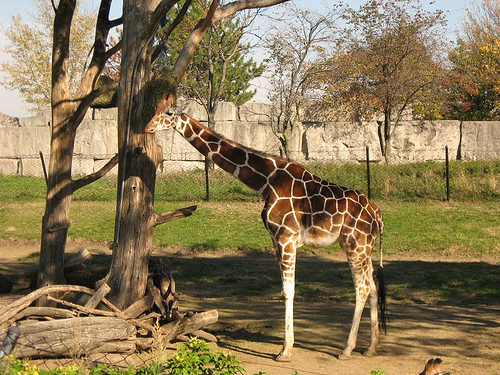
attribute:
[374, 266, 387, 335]
hairs — long, black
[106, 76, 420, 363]
giraffe — penned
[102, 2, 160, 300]
trunk — tree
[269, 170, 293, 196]
polygon — cream, brown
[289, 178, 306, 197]
polygon — cream, brown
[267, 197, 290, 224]
polygon — cream, brown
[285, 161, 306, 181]
polygon — cream, brown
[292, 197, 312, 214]
polygon — brown, cream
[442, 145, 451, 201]
post — black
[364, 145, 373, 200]
post — black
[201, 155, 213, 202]
post — black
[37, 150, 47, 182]
post — black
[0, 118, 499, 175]
wall — slabs, concrete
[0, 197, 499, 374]
enclosure — zoo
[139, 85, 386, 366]
giraffe — standing, baby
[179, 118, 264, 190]
neck — long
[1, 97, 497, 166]
wall — stone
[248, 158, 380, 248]
spots — unique, brown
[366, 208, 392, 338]
tail — long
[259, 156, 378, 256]
spots — large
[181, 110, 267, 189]
neck — Spotted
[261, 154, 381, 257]
torso — Spotted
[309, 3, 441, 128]
foilage — lightly colored